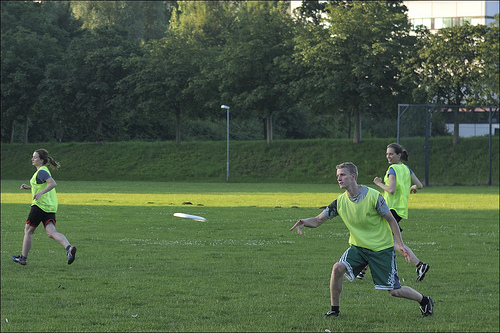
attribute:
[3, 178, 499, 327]
grass — green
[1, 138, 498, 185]
bushes — green, long, lining, here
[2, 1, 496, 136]
trees — green, leafy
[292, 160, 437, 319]
person — blonde, smiling, running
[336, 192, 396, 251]
shirt — green, bright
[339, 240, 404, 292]
shorts — green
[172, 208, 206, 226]
frisbee — white, flying, airborne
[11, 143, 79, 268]
girl — young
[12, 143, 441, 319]
people — young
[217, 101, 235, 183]
pole — small, lit, off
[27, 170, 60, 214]
shirt — green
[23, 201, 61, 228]
shorts — black, red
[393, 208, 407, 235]
shoes — black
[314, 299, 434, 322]
shoes — black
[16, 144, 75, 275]
woman — brunette